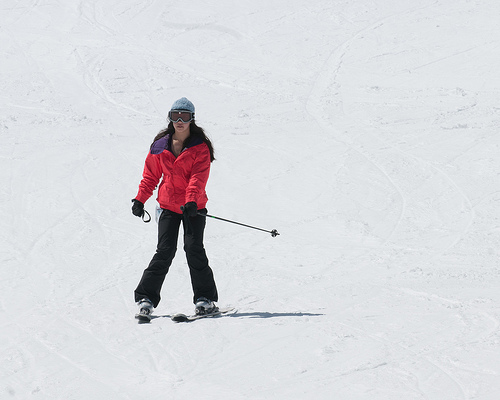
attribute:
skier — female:
[119, 77, 261, 342]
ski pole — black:
[173, 200, 291, 247]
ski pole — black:
[191, 207, 288, 243]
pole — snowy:
[179, 205, 281, 238]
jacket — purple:
[140, 131, 210, 212]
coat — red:
[135, 130, 213, 214]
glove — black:
[115, 196, 158, 222]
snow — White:
[285, 117, 475, 380]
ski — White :
[173, 308, 237, 322]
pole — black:
[241, 210, 290, 237]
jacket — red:
[152, 145, 196, 205]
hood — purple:
[142, 132, 202, 149]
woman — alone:
[132, 100, 226, 318]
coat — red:
[137, 128, 221, 211]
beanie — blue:
[171, 95, 196, 114]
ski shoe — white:
[193, 294, 221, 314]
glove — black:
[128, 199, 146, 219]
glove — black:
[179, 202, 199, 220]